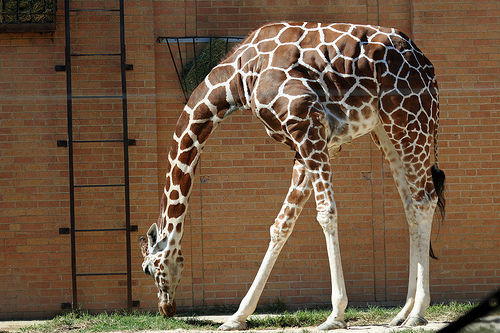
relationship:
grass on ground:
[19, 311, 219, 330] [1, 310, 498, 332]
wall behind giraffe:
[1, 0, 499, 317] [138, 18, 448, 328]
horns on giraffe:
[139, 236, 150, 259] [138, 18, 448, 328]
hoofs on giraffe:
[388, 315, 430, 326] [138, 18, 448, 328]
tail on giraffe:
[430, 129, 446, 221] [138, 18, 448, 328]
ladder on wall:
[55, 0, 139, 316] [1, 0, 499, 317]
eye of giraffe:
[144, 264, 151, 277] [138, 18, 448, 328]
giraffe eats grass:
[138, 18, 448, 328] [19, 311, 219, 330]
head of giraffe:
[140, 224, 184, 318] [138, 18, 448, 328]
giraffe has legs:
[138, 18, 448, 328] [217, 159, 351, 331]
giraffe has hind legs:
[138, 18, 448, 328] [375, 128, 435, 330]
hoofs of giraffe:
[388, 315, 430, 326] [138, 18, 448, 328]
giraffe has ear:
[138, 18, 448, 328] [144, 222, 160, 247]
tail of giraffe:
[430, 129, 446, 221] [138, 18, 448, 328]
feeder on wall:
[156, 34, 244, 101] [1, 0, 499, 317]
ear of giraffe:
[144, 222, 160, 247] [138, 18, 448, 328]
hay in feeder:
[178, 39, 232, 99] [156, 34, 244, 101]